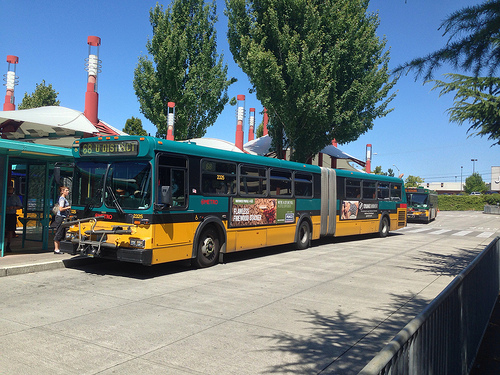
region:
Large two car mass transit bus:
[60, 135, 407, 269]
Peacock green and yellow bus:
[58, 133, 409, 269]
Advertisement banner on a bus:
[225, 193, 297, 228]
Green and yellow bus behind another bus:
[402, 183, 442, 222]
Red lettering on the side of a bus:
[195, 197, 222, 208]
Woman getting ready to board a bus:
[48, 185, 76, 257]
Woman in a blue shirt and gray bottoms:
[50, 183, 74, 257]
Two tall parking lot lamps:
[459, 155, 478, 192]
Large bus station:
[0, 34, 375, 268]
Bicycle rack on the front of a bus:
[57, 212, 133, 260]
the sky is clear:
[16, 15, 89, 82]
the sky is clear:
[376, 43, 438, 113]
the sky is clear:
[115, 26, 172, 102]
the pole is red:
[56, 18, 116, 154]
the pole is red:
[151, 95, 178, 160]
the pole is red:
[228, 84, 277, 191]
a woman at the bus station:
[32, 182, 83, 270]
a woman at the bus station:
[16, 168, 98, 248]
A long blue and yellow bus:
[58, 131, 412, 271]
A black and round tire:
[190, 221, 225, 273]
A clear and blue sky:
[1, 0, 498, 181]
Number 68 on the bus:
[76, 138, 95, 158]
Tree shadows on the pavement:
[252, 241, 487, 372]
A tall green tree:
[129, 1, 239, 142]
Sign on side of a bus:
[227, 194, 297, 229]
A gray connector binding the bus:
[311, 159, 339, 243]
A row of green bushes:
[426, 192, 498, 213]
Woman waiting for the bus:
[47, 179, 75, 256]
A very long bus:
[55, 115, 423, 268]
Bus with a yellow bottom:
[53, 200, 405, 259]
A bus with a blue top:
[68, 124, 454, 222]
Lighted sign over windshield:
[66, 135, 156, 163]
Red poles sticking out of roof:
[71, 5, 119, 127]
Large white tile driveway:
[118, 282, 274, 369]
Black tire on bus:
[193, 227, 225, 273]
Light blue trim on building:
[3, 133, 69, 158]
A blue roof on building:
[251, 126, 341, 159]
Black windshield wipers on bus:
[88, 168, 147, 208]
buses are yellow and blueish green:
[54, 119, 452, 278]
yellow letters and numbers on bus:
[62, 133, 147, 163]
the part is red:
[66, 72, 116, 130]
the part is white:
[66, 53, 115, 77]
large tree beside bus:
[221, 2, 381, 197]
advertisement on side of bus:
[207, 188, 314, 232]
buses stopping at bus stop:
[0, 103, 448, 279]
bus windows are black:
[156, 149, 400, 212]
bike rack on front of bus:
[62, 213, 138, 266]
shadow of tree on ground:
[211, 225, 494, 374]